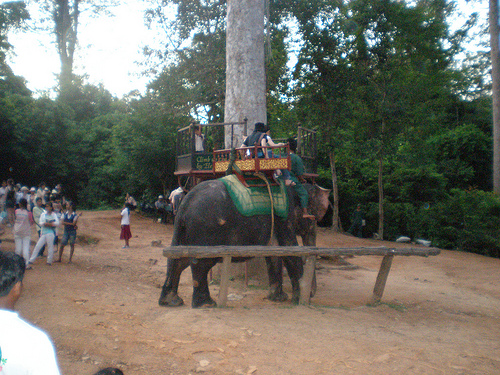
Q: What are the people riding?
A: Elephant.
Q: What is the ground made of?
A: Dirt.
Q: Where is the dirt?
A: On the ground.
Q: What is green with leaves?
A: The trees.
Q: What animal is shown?
A: Elephant.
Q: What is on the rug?
A: A green rug.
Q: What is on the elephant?
A: A green rug.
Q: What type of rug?
A: Green rug.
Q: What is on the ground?
A: Large post.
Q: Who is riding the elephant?
A: The people.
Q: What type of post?
A: A brown post.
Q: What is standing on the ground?
A: The elephant is.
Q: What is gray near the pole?
A: The elephant is.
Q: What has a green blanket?
A: The elephant does.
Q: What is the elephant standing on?
A: The dirt ground.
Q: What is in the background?
A: Green trees.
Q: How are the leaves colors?
A: Green.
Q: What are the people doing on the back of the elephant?
A: Riding it.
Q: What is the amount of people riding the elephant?
A: Three.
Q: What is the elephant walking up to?
A: A deck around a tree.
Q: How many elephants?
A: 1.